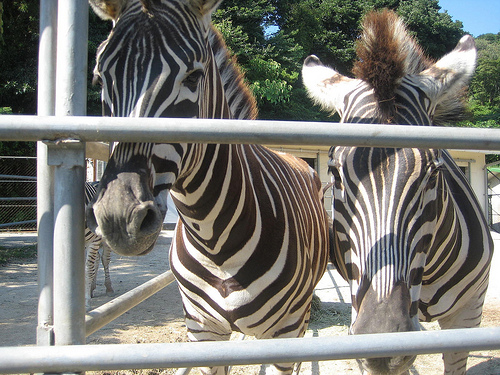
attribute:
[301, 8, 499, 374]
zebra — standing, black, striped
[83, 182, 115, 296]
zebra — barly visible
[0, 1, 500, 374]
fence — gray, metal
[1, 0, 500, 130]
trees — green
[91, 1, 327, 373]
zebra — standing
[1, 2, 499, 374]
poles — silver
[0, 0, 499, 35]
sky — blue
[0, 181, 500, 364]
ground — dark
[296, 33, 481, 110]
ears — perked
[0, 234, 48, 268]
grass — green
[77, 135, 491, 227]
building — barly visible